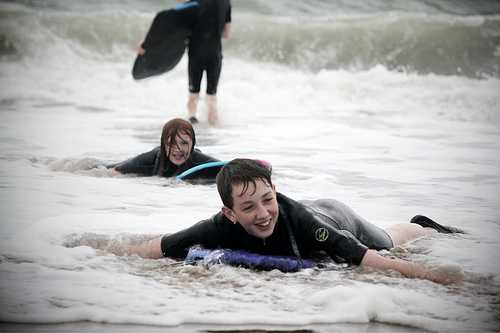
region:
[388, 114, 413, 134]
wave in the water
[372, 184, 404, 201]
wave in the water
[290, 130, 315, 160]
wave in the water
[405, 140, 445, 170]
wave in the water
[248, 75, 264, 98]
wave in the water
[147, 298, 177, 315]
wave in the water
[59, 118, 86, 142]
wave in the water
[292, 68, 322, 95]
wave in the water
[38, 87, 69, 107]
wave in the water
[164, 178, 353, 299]
the boy is wearing a wet suit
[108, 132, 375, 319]
the boy is wearing a wet suit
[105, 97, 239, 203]
the girl with surfboard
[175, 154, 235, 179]
light blue surf board under girl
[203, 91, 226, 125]
bare leg on person in back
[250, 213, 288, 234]
bright smile on boy's face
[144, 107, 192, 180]
long wet hair in girl's face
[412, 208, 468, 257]
wet shoes on boy's feet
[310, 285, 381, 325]
white foam of incoming water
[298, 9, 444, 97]
large grey waves in the distance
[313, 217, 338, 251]
white emblem on black outfit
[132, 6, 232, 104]
black and blue surfboard in woman's arms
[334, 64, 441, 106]
white foamy water in distance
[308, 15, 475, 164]
Waves crashing in the water.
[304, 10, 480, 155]
Waves crashing in the ocean.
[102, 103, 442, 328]
Kids laying in the ocean.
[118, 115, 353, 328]
Kids laying on bodyboards.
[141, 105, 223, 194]
A girl laying on a bright blue board.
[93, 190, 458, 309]
a kids extending his arm in the ocean.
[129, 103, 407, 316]
Kids wearing black wet suits.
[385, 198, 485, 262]
a kid wearing shoes in the water.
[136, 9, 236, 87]
a person carrying a body board.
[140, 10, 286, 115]
a person standing in the ocean.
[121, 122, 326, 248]
Kids floating on the ocean.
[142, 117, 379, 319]
kids laying in water.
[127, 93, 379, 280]
kids swimming in the ocean.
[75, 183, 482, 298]
A kids extending his arms in the water.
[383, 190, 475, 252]
A kid wearing shoes in the water.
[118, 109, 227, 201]
A girl laying on a board.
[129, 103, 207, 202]
a girl body boarding in the ocean.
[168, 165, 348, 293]
a boy laying on a blue body board.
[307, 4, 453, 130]
waves crashing in the ocean.